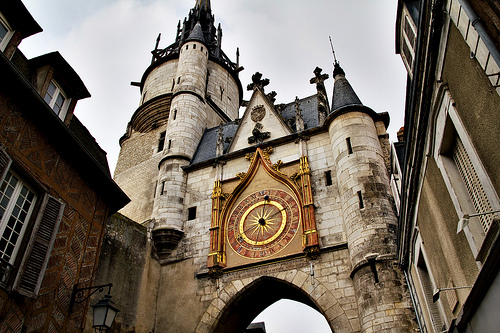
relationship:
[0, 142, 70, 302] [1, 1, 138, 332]
window on building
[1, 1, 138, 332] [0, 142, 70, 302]
building has window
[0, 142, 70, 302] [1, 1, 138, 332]
window of building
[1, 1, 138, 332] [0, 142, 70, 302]
building with window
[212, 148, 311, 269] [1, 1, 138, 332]
clock on building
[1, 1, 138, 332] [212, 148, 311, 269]
building has clock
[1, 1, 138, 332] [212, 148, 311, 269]
building and clock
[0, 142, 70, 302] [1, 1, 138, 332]
window has building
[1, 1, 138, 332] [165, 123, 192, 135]
building of stone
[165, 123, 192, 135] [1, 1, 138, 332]
stone of building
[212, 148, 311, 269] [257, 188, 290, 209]
clock with numerals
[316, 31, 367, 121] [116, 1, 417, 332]
spires on castle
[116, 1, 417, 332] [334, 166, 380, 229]
castle of bricks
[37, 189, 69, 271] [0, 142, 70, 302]
shutters on window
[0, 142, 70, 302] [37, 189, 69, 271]
window with shutters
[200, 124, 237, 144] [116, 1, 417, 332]
roof on castle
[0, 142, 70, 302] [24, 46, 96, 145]
window on attic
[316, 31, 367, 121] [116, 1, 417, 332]
spire on castle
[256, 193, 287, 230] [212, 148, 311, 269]
hands on clock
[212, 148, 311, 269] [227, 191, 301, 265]
clock has face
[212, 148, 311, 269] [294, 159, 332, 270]
clock has edging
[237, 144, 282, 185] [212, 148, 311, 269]
arch around clock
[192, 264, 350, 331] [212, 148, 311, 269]
archway underneath clock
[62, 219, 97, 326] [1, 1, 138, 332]
side of building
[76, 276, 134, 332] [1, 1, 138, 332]
light attached to building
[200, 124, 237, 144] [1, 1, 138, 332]
roof on building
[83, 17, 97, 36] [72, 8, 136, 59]
part of cloud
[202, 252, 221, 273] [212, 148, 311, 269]
edge of clock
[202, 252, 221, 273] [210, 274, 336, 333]
edge of entryway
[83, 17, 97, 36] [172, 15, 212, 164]
part of tower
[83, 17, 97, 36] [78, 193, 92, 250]
part of wall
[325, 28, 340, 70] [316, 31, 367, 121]
spike on spire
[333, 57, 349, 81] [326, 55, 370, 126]
top of spire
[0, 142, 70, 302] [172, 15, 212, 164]
window on tower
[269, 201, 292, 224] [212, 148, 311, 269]
hand of clock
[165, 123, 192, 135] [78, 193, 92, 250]
stone in wall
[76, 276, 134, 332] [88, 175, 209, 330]
lamp on street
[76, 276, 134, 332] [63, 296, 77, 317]
lamp on pole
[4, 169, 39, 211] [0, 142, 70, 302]
frame of window